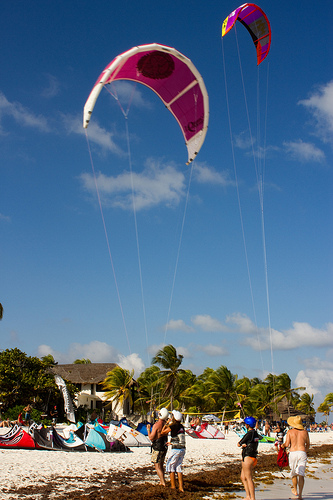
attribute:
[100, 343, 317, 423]
trees — palm, blowing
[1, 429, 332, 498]
sand — white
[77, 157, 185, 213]
cloud — white, puffy, whispy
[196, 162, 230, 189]
cloud — white, puffy, whispy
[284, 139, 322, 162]
cloud — white, puffy, whispy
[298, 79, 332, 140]
cloud — white, puffy, whispy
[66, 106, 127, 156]
cloud — white, puffy, whispy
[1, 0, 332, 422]
sky — blue, beautiful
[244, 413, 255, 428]
helmet — blue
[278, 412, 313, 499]
man — topless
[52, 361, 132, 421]
house — white, two-storied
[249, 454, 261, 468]
bikini — orange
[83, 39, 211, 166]
kite — purple, large, arched, white, bright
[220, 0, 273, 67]
kite — high-flying, multi-colored, bright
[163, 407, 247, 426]
net — yellow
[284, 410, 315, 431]
hat — straw